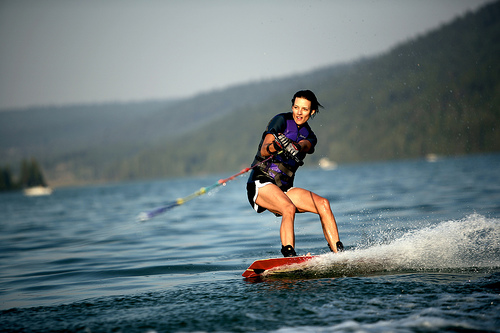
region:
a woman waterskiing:
[214, 67, 363, 273]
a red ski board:
[237, 254, 298, 279]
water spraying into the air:
[383, 220, 481, 265]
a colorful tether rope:
[145, 163, 252, 220]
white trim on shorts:
[255, 180, 265, 190]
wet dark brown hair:
[303, 90, 318, 102]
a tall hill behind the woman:
[337, 5, 491, 149]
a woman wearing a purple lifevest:
[231, 72, 346, 266]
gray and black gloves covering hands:
[272, 136, 297, 158]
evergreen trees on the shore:
[0, 159, 47, 190]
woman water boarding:
[228, 78, 370, 295]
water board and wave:
[220, 215, 492, 296]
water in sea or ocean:
[218, 286, 392, 331]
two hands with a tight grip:
[262, 127, 310, 172]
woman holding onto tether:
[149, 84, 329, 217]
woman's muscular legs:
[254, 188, 354, 248]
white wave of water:
[327, 213, 498, 285]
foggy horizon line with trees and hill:
[0, 50, 230, 148]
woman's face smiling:
[278, 86, 327, 131]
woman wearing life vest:
[243, 83, 327, 191]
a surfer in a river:
[216, 64, 401, 299]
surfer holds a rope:
[29, 75, 347, 270]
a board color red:
[224, 238, 396, 292]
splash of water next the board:
[239, 208, 499, 295]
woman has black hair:
[248, 80, 335, 180]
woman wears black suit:
[233, 70, 356, 265]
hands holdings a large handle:
[254, 126, 312, 179]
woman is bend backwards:
[234, 78, 357, 261]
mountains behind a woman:
[6, 3, 497, 171]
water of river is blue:
[6, 154, 496, 331]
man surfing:
[231, 72, 349, 279]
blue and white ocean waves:
[71, 198, 152, 252]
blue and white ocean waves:
[178, 195, 209, 246]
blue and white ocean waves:
[40, 251, 94, 298]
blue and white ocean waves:
[145, 253, 195, 310]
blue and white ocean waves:
[404, 199, 498, 277]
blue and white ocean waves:
[345, 163, 419, 223]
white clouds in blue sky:
[26, 22, 113, 92]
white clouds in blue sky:
[155, 21, 216, 66]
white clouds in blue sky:
[250, 18, 321, 65]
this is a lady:
[250, 82, 360, 260]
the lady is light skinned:
[268, 191, 296, 206]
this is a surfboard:
[261, 253, 299, 272]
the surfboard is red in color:
[250, 256, 276, 281]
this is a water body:
[26, 171, 126, 311]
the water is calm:
[55, 194, 110, 266]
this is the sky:
[133, 20, 208, 54]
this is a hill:
[388, 29, 483, 98]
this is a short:
[246, 172, 255, 194]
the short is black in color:
[243, 182, 255, 197]